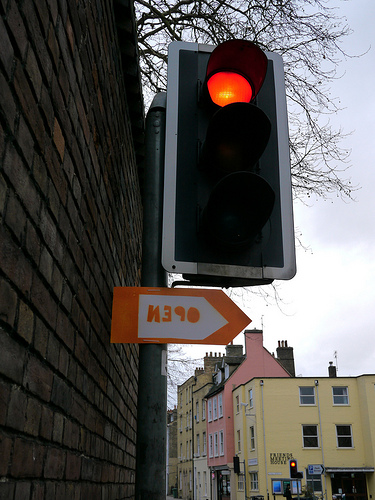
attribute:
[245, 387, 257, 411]
window — small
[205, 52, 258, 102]
light — black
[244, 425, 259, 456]
window — small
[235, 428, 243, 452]
window — small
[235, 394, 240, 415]
window — small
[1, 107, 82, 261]
wall — brick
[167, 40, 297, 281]
traffic light — black,  for traffic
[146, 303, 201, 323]
writing — orange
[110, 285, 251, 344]
sign — orange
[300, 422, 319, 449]
window — small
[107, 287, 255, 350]
arrow — orange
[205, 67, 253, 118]
light — red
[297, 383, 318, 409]
window — small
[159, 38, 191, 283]
border —  white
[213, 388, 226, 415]
window — small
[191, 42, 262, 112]
light — red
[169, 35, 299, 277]
sign — traffic